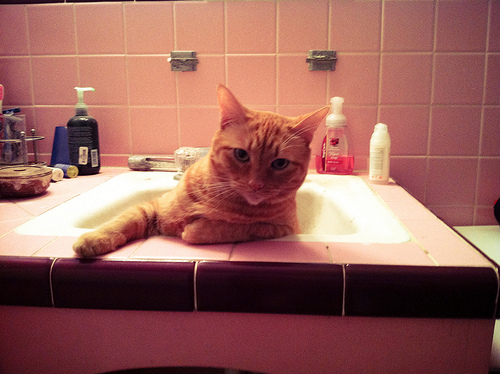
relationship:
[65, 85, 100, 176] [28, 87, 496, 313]
bottle in sink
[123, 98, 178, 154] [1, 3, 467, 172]
tile on wall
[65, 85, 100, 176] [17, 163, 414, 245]
bottle in sink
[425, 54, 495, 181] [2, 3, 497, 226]
tile on wall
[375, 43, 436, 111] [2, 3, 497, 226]
tile on wall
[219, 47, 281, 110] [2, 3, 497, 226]
tile on wall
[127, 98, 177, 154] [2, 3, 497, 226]
tile on wall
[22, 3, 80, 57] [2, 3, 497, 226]
tile on wall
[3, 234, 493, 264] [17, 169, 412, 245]
pink tile around white sink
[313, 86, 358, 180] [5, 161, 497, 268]
soap bottle on counter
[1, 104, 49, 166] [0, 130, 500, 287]
toothbrush holder on counter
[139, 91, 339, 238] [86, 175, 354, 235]
cat in sink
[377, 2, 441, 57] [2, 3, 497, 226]
tile on wall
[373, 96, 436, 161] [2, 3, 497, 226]
tile on wall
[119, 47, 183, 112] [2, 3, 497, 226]
tile on wall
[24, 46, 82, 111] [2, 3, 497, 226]
tile on wall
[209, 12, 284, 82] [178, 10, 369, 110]
tiles on wall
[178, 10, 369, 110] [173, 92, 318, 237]
wall behind cat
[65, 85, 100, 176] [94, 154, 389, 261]
bottle in sink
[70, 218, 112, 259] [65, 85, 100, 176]
paw of bottle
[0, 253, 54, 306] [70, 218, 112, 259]
tile near paw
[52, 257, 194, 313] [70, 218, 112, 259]
tile near paw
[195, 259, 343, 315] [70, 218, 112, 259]
tile near paw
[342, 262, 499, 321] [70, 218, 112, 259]
tile near paw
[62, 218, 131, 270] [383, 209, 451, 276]
paw resting on tile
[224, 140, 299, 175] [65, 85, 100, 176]
eyes of bottle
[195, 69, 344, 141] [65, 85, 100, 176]
ears of bottle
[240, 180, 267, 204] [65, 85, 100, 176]
nose of bottle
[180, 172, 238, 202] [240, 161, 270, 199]
whiskers near nose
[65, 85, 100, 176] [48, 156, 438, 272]
bottle in sink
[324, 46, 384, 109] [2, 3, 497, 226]
tile on wall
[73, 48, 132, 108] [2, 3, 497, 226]
tile on wall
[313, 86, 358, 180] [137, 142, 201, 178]
soap bottle next to faucet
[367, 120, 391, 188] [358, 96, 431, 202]
bottle next to soap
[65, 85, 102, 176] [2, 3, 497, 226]
bottle facing wall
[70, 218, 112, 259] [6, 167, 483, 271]
paw on sink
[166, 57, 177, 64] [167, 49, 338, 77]
bolt for towel holder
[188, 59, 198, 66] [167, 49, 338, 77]
bolt for towel holder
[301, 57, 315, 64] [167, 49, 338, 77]
bolt for towel holder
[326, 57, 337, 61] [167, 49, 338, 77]
bolt for towel holder